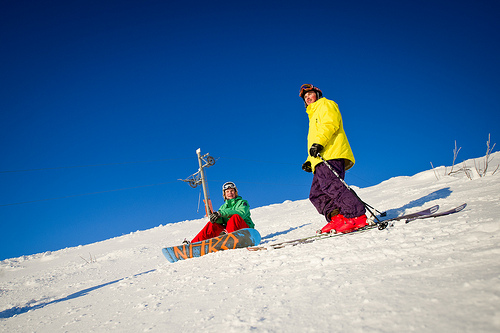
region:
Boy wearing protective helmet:
[218, 180, 243, 200]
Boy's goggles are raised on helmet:
[214, 179, 244, 193]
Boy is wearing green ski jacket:
[214, 195, 253, 225]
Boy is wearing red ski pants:
[180, 205, 257, 248]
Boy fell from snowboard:
[148, 220, 279, 270]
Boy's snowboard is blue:
[141, 220, 278, 277]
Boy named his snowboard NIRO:
[136, 222, 273, 277]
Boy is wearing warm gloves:
[200, 205, 222, 226]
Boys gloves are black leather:
[191, 207, 226, 222]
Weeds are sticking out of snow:
[408, 112, 498, 207]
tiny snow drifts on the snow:
[129, 275, 237, 310]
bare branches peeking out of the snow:
[424, 126, 474, 181]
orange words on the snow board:
[168, 230, 251, 262]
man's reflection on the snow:
[25, 281, 172, 291]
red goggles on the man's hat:
[287, 75, 332, 95]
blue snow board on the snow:
[143, 223, 293, 261]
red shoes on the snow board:
[290, 207, 381, 241]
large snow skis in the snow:
[235, 204, 457, 233]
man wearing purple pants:
[288, 160, 377, 226]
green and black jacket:
[210, 195, 281, 218]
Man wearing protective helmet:
[294, 83, 324, 104]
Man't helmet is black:
[292, 79, 334, 104]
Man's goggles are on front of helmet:
[293, 80, 317, 100]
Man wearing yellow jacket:
[288, 99, 361, 169]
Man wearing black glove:
[306, 142, 335, 159]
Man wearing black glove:
[291, 152, 316, 177]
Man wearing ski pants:
[305, 157, 367, 224]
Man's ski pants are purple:
[298, 159, 388, 227]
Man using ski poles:
[311, 142, 389, 228]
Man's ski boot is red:
[338, 206, 373, 251]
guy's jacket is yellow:
[286, 96, 354, 176]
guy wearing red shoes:
[315, 210, 375, 235]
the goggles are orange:
[285, 71, 316, 103]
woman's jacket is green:
[208, 188, 253, 218]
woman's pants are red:
[186, 210, 259, 248]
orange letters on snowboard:
[167, 233, 238, 253]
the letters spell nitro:
[158, 220, 251, 251]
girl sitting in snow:
[180, 152, 275, 258]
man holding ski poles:
[295, 117, 415, 257]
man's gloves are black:
[283, 132, 340, 183]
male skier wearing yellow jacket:
[293, 82, 393, 237]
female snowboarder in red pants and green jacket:
[158, 177, 266, 264]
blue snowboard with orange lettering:
[158, 226, 271, 263]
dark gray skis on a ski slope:
[243, 198, 470, 257]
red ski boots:
[311, 203, 373, 236]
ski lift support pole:
[175, 146, 222, 224]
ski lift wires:
[1, 146, 417, 211]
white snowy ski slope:
[0, 146, 498, 331]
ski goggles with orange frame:
[293, 82, 320, 97]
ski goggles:
[220, 180, 240, 192]